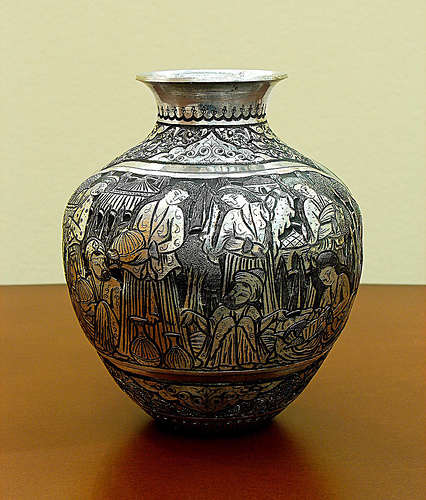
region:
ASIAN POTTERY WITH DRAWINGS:
[58, 51, 353, 390]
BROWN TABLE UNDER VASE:
[2, 285, 424, 493]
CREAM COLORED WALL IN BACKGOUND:
[2, 8, 402, 275]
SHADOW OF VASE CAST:
[109, 419, 343, 498]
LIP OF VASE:
[142, 54, 267, 117]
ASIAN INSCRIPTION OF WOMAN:
[131, 181, 190, 322]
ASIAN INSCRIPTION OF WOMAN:
[220, 187, 283, 316]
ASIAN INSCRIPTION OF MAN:
[75, 246, 124, 334]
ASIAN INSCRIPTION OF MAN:
[193, 262, 265, 372]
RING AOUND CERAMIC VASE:
[102, 350, 327, 372]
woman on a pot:
[119, 170, 190, 337]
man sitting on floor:
[203, 255, 287, 387]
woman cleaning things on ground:
[299, 248, 360, 381]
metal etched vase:
[86, 39, 351, 483]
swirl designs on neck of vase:
[105, 100, 322, 191]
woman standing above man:
[204, 173, 291, 351]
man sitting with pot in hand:
[66, 239, 142, 390]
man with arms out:
[174, 276, 329, 380]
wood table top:
[18, 358, 121, 480]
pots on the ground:
[120, 303, 209, 386]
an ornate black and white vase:
[59, 61, 368, 427]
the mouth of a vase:
[133, 64, 294, 89]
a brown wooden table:
[0, 279, 424, 498]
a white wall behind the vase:
[0, 0, 425, 286]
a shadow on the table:
[83, 409, 336, 498]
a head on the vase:
[162, 175, 202, 207]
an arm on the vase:
[159, 209, 189, 254]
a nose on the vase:
[231, 287, 243, 298]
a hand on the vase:
[132, 245, 152, 266]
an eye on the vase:
[171, 188, 180, 196]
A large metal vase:
[45, 44, 385, 446]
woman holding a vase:
[109, 177, 210, 379]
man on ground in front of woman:
[173, 184, 306, 379]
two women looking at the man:
[139, 176, 283, 362]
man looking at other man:
[74, 234, 283, 373]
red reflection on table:
[78, 408, 319, 499]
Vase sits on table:
[48, 55, 382, 487]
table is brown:
[6, 270, 424, 461]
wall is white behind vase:
[7, 9, 418, 273]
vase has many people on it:
[64, 63, 351, 449]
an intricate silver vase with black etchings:
[48, 67, 361, 427]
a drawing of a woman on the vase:
[116, 181, 193, 356]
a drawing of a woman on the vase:
[217, 184, 276, 311]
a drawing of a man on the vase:
[76, 240, 122, 345]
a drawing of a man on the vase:
[207, 268, 261, 365]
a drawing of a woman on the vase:
[317, 249, 352, 332]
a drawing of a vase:
[112, 223, 143, 263]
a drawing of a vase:
[163, 330, 192, 365]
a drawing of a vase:
[129, 314, 160, 363]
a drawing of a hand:
[132, 248, 147, 264]